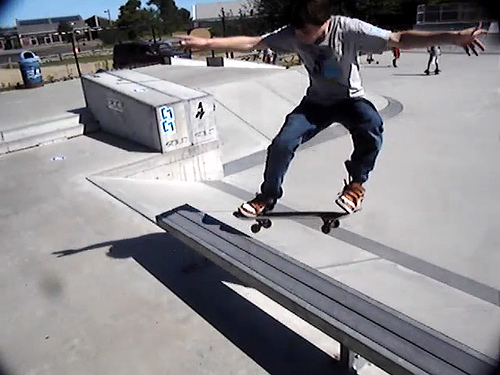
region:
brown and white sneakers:
[325, 179, 378, 218]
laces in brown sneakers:
[338, 179, 371, 202]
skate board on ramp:
[239, 187, 372, 230]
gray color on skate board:
[254, 199, 341, 219]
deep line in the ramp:
[300, 241, 384, 277]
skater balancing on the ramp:
[138, 7, 478, 230]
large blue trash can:
[15, 43, 56, 95]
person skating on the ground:
[421, 44, 448, 78]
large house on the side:
[17, 9, 122, 48]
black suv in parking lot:
[107, 33, 204, 66]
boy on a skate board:
[236, 7, 378, 244]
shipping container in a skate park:
[68, 47, 222, 153]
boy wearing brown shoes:
[238, 157, 376, 227]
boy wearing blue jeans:
[248, 84, 381, 214]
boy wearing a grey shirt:
[248, 21, 408, 111]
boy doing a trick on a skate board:
[223, 166, 395, 248]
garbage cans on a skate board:
[21, 43, 52, 90]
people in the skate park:
[240, 19, 457, 83]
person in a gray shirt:
[251, 17, 402, 98]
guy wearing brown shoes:
[239, 173, 368, 225]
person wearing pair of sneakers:
[152, 5, 493, 229]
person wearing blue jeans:
[146, 3, 481, 220]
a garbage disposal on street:
[14, 43, 50, 89]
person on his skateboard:
[154, 5, 492, 230]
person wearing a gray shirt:
[140, 2, 480, 229]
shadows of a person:
[65, 216, 227, 298]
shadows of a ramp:
[135, 239, 351, 371]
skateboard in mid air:
[231, 197, 357, 240]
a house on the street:
[6, 11, 96, 47]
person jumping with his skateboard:
[133, 6, 493, 236]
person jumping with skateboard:
[165, 4, 490, 244]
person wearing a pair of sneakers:
[152, 4, 490, 236]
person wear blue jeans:
[134, 5, 492, 237]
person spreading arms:
[154, 0, 496, 238]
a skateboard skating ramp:
[141, 196, 498, 371]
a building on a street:
[10, 10, 92, 47]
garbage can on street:
[15, 49, 49, 91]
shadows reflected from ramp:
[131, 260, 347, 374]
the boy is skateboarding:
[225, 3, 401, 320]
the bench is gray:
[146, 189, 365, 369]